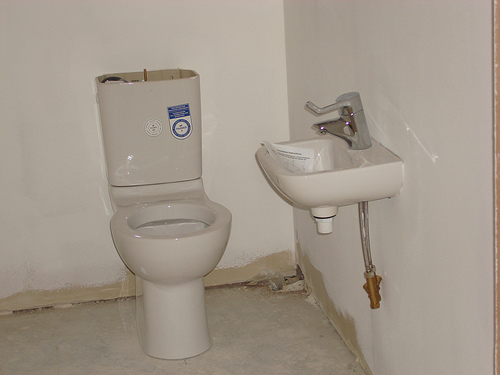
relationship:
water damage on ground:
[252, 262, 333, 315] [10, 259, 366, 374]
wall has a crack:
[282, 2, 480, 367] [287, 258, 375, 369]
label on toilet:
[164, 101, 201, 151] [82, 71, 247, 374]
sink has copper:
[248, 127, 413, 240] [358, 266, 391, 313]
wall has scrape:
[282, 2, 480, 367] [287, 258, 314, 301]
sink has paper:
[248, 127, 413, 240] [260, 135, 320, 180]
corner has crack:
[262, 233, 330, 313] [292, 264, 306, 291]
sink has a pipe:
[248, 127, 413, 240] [345, 192, 393, 283]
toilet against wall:
[82, 71, 247, 374] [6, 6, 293, 314]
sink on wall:
[248, 127, 413, 240] [282, 2, 480, 367]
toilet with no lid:
[82, 71, 247, 374] [109, 190, 236, 248]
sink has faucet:
[248, 127, 413, 240] [296, 86, 384, 153]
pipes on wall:
[345, 192, 393, 283] [282, 2, 480, 367]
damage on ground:
[10, 259, 366, 374] [0, 274, 367, 375]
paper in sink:
[260, 135, 320, 180] [248, 127, 413, 240]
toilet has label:
[82, 71, 247, 374] [164, 101, 201, 151]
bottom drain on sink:
[305, 206, 337, 237] [248, 127, 413, 240]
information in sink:
[260, 135, 320, 180] [248, 127, 413, 240]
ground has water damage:
[10, 259, 366, 374] [252, 262, 333, 315]